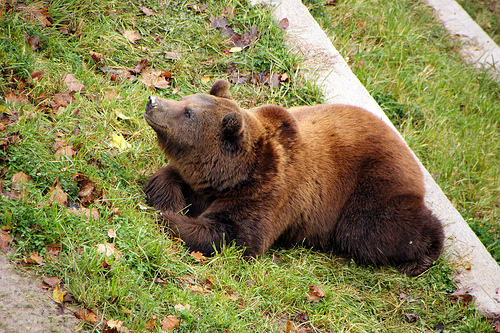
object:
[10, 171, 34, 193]
leaves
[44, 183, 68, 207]
leaf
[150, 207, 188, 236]
paw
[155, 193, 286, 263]
leg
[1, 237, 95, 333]
dirt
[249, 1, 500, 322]
step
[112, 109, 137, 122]
leaf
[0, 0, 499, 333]
ground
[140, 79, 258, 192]
head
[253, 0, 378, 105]
barrier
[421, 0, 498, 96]
barrier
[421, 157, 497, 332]
barrier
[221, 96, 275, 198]
neck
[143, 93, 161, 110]
nose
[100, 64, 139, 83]
leaves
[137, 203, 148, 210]
leaf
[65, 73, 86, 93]
leaf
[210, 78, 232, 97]
ear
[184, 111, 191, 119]
eye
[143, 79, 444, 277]
bear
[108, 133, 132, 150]
leaves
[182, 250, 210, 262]
blades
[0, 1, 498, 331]
grass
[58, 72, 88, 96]
leaf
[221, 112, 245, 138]
ear